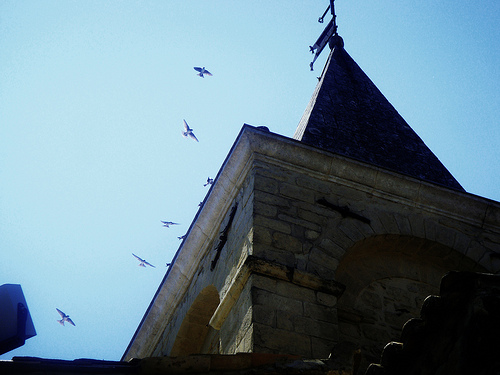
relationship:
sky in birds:
[83, 38, 124, 67] [172, 49, 212, 79]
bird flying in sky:
[188, 64, 214, 84] [11, 15, 291, 266]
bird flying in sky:
[130, 250, 155, 269] [0, 0, 499, 362]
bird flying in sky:
[54, 308, 75, 328] [0, 0, 499, 362]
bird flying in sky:
[183, 119, 200, 142] [0, 0, 499, 362]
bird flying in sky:
[194, 67, 212, 78] [0, 0, 499, 362]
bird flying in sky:
[159, 219, 180, 227] [0, 0, 499, 362]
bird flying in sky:
[181, 112, 197, 138] [0, 0, 499, 362]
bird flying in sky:
[159, 216, 176, 229] [0, 0, 499, 362]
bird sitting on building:
[187, 194, 212, 219] [118, 0, 499, 371]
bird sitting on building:
[174, 232, 189, 242] [152, 54, 492, 374]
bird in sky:
[194, 67, 212, 78] [68, 93, 153, 199]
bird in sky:
[183, 119, 200, 142] [68, 93, 153, 199]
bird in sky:
[159, 219, 180, 227] [68, 93, 153, 199]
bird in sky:
[132, 253, 155, 267] [68, 93, 153, 199]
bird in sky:
[54, 308, 75, 328] [68, 93, 153, 199]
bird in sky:
[183, 119, 200, 142] [0, 0, 499, 362]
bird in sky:
[54, 308, 75, 328] [0, 0, 499, 362]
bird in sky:
[132, 253, 155, 267] [0, 0, 499, 362]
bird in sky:
[159, 219, 180, 227] [0, 0, 499, 362]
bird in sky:
[194, 67, 212, 78] [0, 0, 499, 362]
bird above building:
[194, 67, 212, 78] [191, 60, 388, 291]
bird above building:
[54, 308, 75, 328] [191, 60, 388, 291]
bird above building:
[132, 253, 155, 267] [191, 60, 388, 291]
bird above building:
[159, 219, 180, 227] [191, 60, 388, 291]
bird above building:
[183, 119, 200, 142] [191, 60, 388, 291]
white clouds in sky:
[37, 22, 111, 100] [0, 0, 499, 362]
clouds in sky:
[392, 15, 459, 94] [0, 0, 499, 362]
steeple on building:
[290, 45, 470, 192] [1, 34, 496, 374]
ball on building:
[326, 32, 346, 49] [118, 0, 499, 371]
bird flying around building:
[194, 67, 212, 78] [118, 0, 499, 371]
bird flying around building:
[183, 119, 200, 142] [118, 0, 499, 371]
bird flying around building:
[159, 219, 180, 227] [118, 0, 499, 371]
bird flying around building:
[132, 253, 155, 267] [118, 0, 499, 371]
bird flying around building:
[54, 308, 75, 328] [118, 0, 499, 371]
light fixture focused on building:
[0, 282, 49, 359] [118, 0, 499, 371]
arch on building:
[351, 254, 496, 364] [118, 0, 499, 371]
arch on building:
[176, 289, 226, 367] [118, 0, 499, 371]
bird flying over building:
[194, 67, 212, 78] [307, 103, 447, 303]